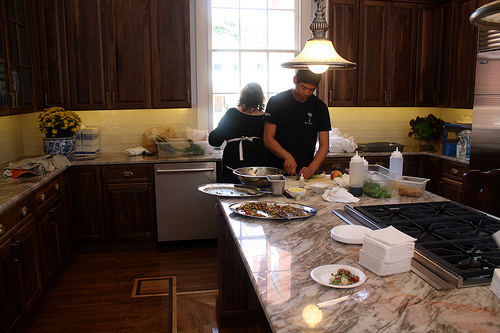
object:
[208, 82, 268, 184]
woman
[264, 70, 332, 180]
man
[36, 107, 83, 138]
flower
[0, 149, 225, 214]
counter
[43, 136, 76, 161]
pot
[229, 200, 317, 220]
tray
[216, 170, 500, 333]
counter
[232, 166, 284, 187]
basin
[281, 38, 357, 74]
light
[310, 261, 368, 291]
plate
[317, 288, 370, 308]
fork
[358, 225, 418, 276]
napkins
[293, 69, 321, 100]
head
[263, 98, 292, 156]
arm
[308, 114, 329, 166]
arm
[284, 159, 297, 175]
hand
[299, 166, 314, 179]
hand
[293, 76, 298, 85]
ear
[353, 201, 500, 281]
stove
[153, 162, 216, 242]
dishwasher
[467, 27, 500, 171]
refrigerator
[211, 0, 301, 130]
window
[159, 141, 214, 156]
containers